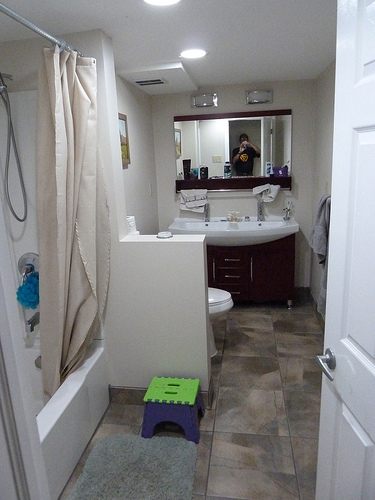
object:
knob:
[315, 347, 336, 383]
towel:
[308, 194, 331, 321]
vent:
[135, 77, 168, 86]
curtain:
[37, 44, 111, 398]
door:
[314, 0, 374, 498]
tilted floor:
[205, 356, 303, 499]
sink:
[166, 214, 300, 247]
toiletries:
[220, 211, 243, 222]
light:
[181, 48, 207, 60]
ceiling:
[0, 0, 337, 97]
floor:
[58, 286, 325, 498]